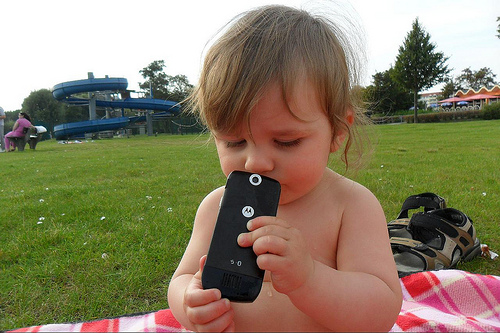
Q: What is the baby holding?
A: A phone.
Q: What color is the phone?
A: Black.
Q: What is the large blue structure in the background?
A: A waterslide.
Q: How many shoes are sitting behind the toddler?
A: Two.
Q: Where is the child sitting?
A: On a cloth.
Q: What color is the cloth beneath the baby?
A: Red and white.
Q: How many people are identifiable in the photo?
A: Two.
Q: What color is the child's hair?
A: Brown.